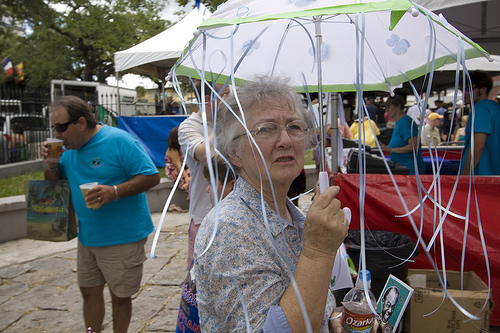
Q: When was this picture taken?
A: Daytime.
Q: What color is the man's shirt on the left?
A: Blue.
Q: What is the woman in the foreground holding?
A: Umbrella.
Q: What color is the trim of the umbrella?
A: Green.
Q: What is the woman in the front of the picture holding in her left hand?
A: Water bottle.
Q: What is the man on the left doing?
A: Drinking.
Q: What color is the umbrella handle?
A: White.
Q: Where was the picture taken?
A: At a festival.